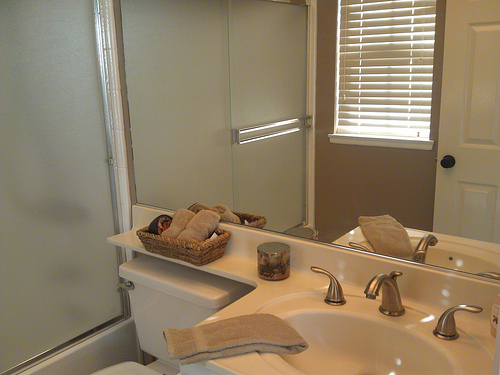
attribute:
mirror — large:
[119, 1, 499, 282]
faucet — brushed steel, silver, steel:
[364, 270, 406, 318]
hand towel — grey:
[161, 313, 308, 365]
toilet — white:
[90, 257, 249, 375]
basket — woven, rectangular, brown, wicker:
[136, 225, 233, 266]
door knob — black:
[440, 154, 455, 169]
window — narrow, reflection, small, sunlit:
[336, 0, 437, 141]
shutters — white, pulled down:
[336, 0, 435, 136]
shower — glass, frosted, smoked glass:
[0, 1, 122, 374]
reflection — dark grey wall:
[315, 0, 447, 243]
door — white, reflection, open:
[431, 0, 499, 243]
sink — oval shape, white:
[251, 290, 494, 375]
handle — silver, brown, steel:
[309, 265, 347, 308]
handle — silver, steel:
[432, 304, 485, 341]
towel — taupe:
[159, 208, 197, 238]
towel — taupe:
[178, 210, 221, 241]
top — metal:
[256, 241, 288, 254]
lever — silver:
[116, 280, 134, 293]